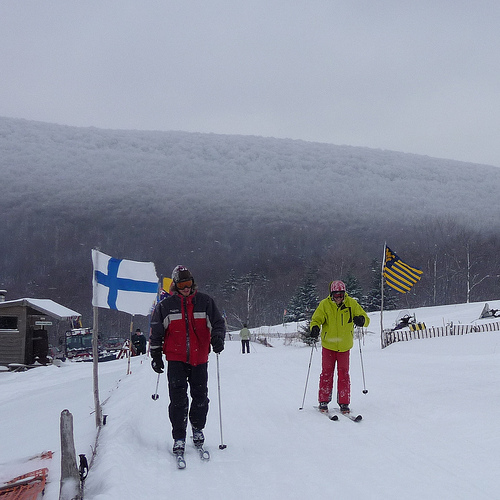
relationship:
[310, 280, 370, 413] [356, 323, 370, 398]
man holding pole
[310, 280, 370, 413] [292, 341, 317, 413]
man holding pole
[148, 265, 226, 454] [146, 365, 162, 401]
man holding pole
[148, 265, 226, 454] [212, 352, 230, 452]
man holding pole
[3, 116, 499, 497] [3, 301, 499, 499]
white snow on hill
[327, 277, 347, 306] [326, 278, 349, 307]
helmet on head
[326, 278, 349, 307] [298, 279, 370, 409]
head of person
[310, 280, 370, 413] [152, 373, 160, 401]
man on pole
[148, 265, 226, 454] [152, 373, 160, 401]
man on pole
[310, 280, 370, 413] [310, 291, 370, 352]
man wearing coat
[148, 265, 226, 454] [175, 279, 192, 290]
man wearing goggles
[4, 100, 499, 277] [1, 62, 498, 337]
mountain in background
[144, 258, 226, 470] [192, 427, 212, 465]
man on ski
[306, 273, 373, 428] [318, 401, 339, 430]
man on ski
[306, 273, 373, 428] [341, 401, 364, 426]
man on ski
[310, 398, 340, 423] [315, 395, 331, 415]
ski on foot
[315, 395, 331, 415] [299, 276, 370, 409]
foot of woman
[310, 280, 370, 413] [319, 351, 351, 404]
man wearing pants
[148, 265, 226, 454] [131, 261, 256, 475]
man wearing coat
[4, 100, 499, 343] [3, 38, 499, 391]
mountain in background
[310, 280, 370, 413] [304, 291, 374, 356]
man wearing coat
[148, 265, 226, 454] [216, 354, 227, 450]
man has pole